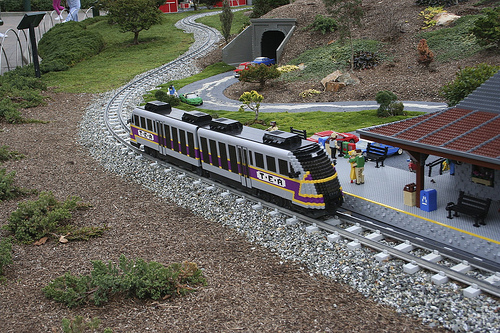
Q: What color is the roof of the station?
A: Red.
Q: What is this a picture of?
A: Train.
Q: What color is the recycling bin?
A: Blue.